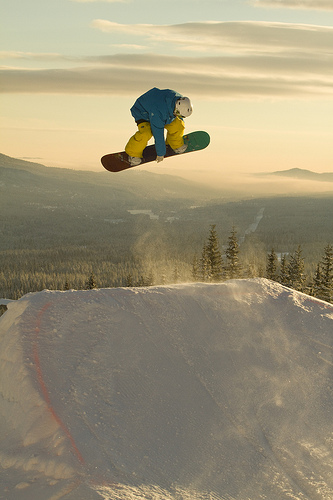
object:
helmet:
[175, 97, 192, 118]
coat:
[129, 88, 182, 156]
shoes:
[129, 139, 188, 166]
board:
[101, 130, 211, 172]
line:
[34, 301, 83, 463]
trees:
[190, 223, 333, 306]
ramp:
[17, 277, 333, 500]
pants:
[125, 116, 186, 158]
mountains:
[0, 154, 333, 263]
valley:
[0, 201, 333, 284]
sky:
[0, 4, 333, 173]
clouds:
[0, 0, 333, 104]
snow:
[0, 276, 333, 500]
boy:
[125, 87, 194, 166]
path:
[0, 277, 332, 499]